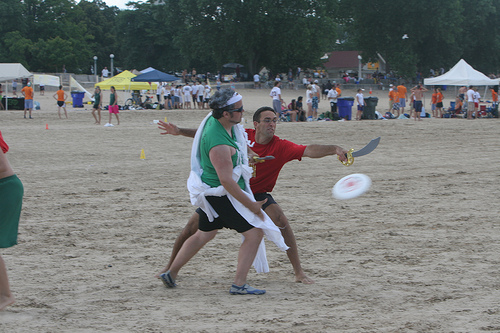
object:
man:
[158, 87, 268, 297]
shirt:
[199, 115, 247, 193]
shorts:
[196, 193, 255, 232]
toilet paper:
[158, 83, 272, 280]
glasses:
[227, 106, 244, 114]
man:
[150, 106, 349, 287]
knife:
[343, 136, 383, 168]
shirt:
[245, 126, 308, 194]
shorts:
[252, 190, 277, 210]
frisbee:
[329, 172, 371, 202]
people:
[270, 80, 286, 124]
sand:
[375, 264, 436, 327]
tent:
[422, 57, 498, 88]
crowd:
[386, 79, 500, 119]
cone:
[135, 146, 147, 162]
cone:
[42, 121, 50, 132]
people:
[433, 86, 450, 118]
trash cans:
[334, 96, 355, 123]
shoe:
[227, 282, 268, 297]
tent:
[94, 70, 158, 92]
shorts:
[109, 103, 121, 114]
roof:
[320, 47, 365, 67]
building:
[321, 49, 386, 83]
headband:
[208, 92, 246, 111]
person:
[408, 83, 429, 122]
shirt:
[397, 84, 409, 98]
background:
[359, 1, 399, 121]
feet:
[157, 264, 183, 298]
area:
[0, 285, 75, 332]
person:
[1, 128, 24, 313]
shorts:
[2, 174, 25, 250]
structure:
[1, 60, 35, 113]